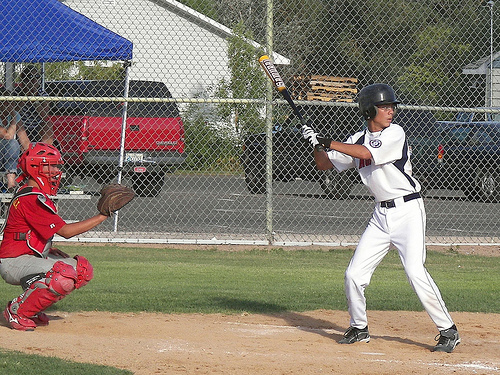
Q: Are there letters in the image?
A: Yes, there are letters.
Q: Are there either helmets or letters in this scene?
A: Yes, there are letters.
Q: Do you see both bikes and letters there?
A: No, there are letters but no bikes.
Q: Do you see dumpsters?
A: No, there are no dumpsters.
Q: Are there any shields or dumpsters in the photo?
A: No, there are no dumpsters or shields.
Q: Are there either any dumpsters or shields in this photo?
A: No, there are no dumpsters or shields.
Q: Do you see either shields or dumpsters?
A: No, there are no dumpsters or shields.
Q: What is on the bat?
A: The letters are on the bat.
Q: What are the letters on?
A: The letters are on the bat.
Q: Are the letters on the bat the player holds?
A: Yes, the letters are on the bat.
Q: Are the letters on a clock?
A: No, the letters are on the bat.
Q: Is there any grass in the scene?
A: Yes, there is grass.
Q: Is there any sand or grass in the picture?
A: Yes, there is grass.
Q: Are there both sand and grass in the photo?
A: No, there is grass but no sand.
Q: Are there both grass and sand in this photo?
A: No, there is grass but no sand.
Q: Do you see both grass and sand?
A: No, there is grass but no sand.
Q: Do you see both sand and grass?
A: No, there is grass but no sand.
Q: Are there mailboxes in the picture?
A: No, there are no mailboxes.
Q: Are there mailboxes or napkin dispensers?
A: No, there are no mailboxes or napkin dispensers.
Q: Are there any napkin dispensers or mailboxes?
A: No, there are no mailboxes or napkin dispensers.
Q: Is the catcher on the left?
A: Yes, the catcher is on the left of the image.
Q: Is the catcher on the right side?
A: No, the catcher is on the left of the image.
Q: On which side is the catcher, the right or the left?
A: The catcher is on the left of the image.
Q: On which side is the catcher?
A: The catcher is on the left of the image.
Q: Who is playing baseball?
A: The catcher is playing baseball.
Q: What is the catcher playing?
A: The catcher is playing baseball.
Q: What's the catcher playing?
A: The catcher is playing baseball.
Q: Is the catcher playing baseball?
A: Yes, the catcher is playing baseball.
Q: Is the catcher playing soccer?
A: No, the catcher is playing baseball.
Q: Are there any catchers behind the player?
A: Yes, there is a catcher behind the player.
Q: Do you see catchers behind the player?
A: Yes, there is a catcher behind the player.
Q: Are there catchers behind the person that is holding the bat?
A: Yes, there is a catcher behind the player.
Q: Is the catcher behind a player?
A: Yes, the catcher is behind a player.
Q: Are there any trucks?
A: Yes, there is a truck.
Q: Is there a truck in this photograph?
A: Yes, there is a truck.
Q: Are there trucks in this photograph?
A: Yes, there is a truck.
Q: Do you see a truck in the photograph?
A: Yes, there is a truck.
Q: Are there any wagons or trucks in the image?
A: Yes, there is a truck.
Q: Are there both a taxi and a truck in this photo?
A: No, there is a truck but no taxis.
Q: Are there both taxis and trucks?
A: No, there is a truck but no taxis.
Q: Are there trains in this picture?
A: No, there are no trains.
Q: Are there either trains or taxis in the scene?
A: No, there are no trains or taxis.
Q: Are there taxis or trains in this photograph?
A: No, there are no trains or taxis.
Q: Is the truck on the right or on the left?
A: The truck is on the left of the image.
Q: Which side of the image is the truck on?
A: The truck is on the left of the image.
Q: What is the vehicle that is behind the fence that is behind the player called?
A: The vehicle is a truck.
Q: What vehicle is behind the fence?
A: The vehicle is a truck.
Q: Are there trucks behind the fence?
A: Yes, there is a truck behind the fence.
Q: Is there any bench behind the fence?
A: No, there is a truck behind the fence.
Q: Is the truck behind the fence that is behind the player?
A: Yes, the truck is behind the fence.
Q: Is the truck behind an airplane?
A: No, the truck is behind the fence.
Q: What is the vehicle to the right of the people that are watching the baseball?
A: The vehicle is a truck.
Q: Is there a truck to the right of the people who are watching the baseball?
A: Yes, there is a truck to the right of the people.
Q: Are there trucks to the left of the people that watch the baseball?
A: No, the truck is to the right of the people.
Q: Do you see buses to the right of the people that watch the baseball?
A: No, there is a truck to the right of the people.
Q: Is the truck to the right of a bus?
A: No, the truck is to the right of the helmet.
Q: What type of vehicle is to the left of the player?
A: The vehicle is a truck.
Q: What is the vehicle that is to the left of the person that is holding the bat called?
A: The vehicle is a truck.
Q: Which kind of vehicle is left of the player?
A: The vehicle is a truck.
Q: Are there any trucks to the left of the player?
A: Yes, there is a truck to the left of the player.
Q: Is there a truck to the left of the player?
A: Yes, there is a truck to the left of the player.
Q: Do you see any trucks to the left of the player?
A: Yes, there is a truck to the left of the player.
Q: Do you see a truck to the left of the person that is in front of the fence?
A: Yes, there is a truck to the left of the player.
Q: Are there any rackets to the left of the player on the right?
A: No, there is a truck to the left of the player.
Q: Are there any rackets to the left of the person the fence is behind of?
A: No, there is a truck to the left of the player.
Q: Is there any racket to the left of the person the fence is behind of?
A: No, there is a truck to the left of the player.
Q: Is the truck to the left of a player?
A: Yes, the truck is to the left of a player.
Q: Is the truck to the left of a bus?
A: No, the truck is to the left of a player.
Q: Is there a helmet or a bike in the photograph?
A: Yes, there is a helmet.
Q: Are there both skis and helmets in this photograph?
A: No, there is a helmet but no skis.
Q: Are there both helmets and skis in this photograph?
A: No, there is a helmet but no skis.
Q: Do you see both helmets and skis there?
A: No, there is a helmet but no skis.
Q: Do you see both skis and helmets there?
A: No, there is a helmet but no skis.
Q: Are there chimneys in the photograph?
A: No, there are no chimneys.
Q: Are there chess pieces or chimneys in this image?
A: No, there are no chimneys or chess pieces.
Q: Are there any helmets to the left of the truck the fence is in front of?
A: Yes, there is a helmet to the left of the truck.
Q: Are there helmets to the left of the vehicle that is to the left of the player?
A: Yes, there is a helmet to the left of the truck.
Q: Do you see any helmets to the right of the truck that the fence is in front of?
A: No, the helmet is to the left of the truck.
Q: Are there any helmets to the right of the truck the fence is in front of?
A: No, the helmet is to the left of the truck.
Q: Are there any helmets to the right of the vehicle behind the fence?
A: No, the helmet is to the left of the truck.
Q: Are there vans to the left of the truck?
A: No, there is a helmet to the left of the truck.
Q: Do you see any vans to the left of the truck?
A: No, there is a helmet to the left of the truck.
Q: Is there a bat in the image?
A: Yes, there is a bat.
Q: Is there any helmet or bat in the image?
A: Yes, there is a bat.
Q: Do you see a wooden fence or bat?
A: Yes, there is a wood bat.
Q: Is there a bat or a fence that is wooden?
A: Yes, the bat is wooden.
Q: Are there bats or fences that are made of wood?
A: Yes, the bat is made of wood.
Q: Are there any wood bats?
A: Yes, there is a bat that is made of wood.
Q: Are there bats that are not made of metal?
A: Yes, there is a bat that is made of wood.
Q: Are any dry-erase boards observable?
A: No, there are no dry-erase boards.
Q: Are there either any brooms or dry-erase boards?
A: No, there are no dry-erase boards or brooms.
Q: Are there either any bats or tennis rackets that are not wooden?
A: No, there is a bat but it is wooden.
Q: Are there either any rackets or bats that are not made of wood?
A: No, there is a bat but it is made of wood.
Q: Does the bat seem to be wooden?
A: Yes, the bat is wooden.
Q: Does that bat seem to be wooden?
A: Yes, the bat is wooden.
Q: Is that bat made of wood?
A: Yes, the bat is made of wood.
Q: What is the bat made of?
A: The bat is made of wood.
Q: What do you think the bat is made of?
A: The bat is made of wood.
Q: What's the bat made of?
A: The bat is made of wood.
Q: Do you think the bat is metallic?
A: No, the bat is wooden.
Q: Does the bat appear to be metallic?
A: No, the bat is wooden.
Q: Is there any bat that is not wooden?
A: No, there is a bat but it is wooden.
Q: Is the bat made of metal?
A: No, the bat is made of wood.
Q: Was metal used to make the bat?
A: No, the bat is made of wood.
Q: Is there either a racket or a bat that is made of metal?
A: No, there is a bat but it is made of wood.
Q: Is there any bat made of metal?
A: No, there is a bat but it is made of wood.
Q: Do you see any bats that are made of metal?
A: No, there is a bat but it is made of wood.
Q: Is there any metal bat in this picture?
A: No, there is a bat but it is made of wood.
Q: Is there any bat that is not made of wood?
A: No, there is a bat but it is made of wood.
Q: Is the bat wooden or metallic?
A: The bat is wooden.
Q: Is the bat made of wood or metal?
A: The bat is made of wood.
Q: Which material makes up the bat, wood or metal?
A: The bat is made of wood.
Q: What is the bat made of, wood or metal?
A: The bat is made of wood.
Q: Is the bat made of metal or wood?
A: The bat is made of wood.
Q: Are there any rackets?
A: No, there are no rackets.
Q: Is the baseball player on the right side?
A: Yes, the player is on the right of the image.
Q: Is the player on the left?
A: No, the player is on the right of the image.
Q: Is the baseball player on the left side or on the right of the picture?
A: The player is on the right of the image.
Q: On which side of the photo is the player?
A: The player is on the right of the image.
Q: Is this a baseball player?
A: Yes, this is a baseball player.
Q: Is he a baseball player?
A: Yes, this is a baseball player.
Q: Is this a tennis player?
A: No, this is a baseball player.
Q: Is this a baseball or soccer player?
A: This is a baseball player.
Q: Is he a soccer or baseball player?
A: This is a baseball player.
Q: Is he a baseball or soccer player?
A: This is a baseball player.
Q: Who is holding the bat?
A: The player is holding the bat.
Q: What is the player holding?
A: The player is holding the bat.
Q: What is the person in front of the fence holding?
A: The player is holding the bat.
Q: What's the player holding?
A: The player is holding the bat.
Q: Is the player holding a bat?
A: Yes, the player is holding a bat.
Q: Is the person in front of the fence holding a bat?
A: Yes, the player is holding a bat.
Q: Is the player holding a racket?
A: No, the player is holding a bat.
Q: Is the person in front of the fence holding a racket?
A: No, the player is holding a bat.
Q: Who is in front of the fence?
A: The player is in front of the fence.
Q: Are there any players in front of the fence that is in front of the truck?
A: Yes, there is a player in front of the fence.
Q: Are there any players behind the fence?
A: No, the player is in front of the fence.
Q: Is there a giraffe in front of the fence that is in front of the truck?
A: No, there is a player in front of the fence.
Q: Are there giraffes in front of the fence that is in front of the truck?
A: No, there is a player in front of the fence.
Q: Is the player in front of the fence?
A: Yes, the player is in front of the fence.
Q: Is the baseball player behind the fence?
A: No, the player is in front of the fence.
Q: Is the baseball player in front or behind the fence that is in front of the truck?
A: The player is in front of the fence.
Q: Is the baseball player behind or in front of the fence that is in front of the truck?
A: The player is in front of the fence.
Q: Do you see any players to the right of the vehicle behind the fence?
A: Yes, there is a player to the right of the truck.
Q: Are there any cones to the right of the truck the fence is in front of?
A: No, there is a player to the right of the truck.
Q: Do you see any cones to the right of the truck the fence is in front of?
A: No, there is a player to the right of the truck.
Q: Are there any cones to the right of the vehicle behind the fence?
A: No, there is a player to the right of the truck.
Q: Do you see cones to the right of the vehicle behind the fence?
A: No, there is a player to the right of the truck.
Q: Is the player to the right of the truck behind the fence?
A: Yes, the player is to the right of the truck.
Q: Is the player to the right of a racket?
A: No, the player is to the right of the truck.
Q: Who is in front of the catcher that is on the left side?
A: The player is in front of the catcher.